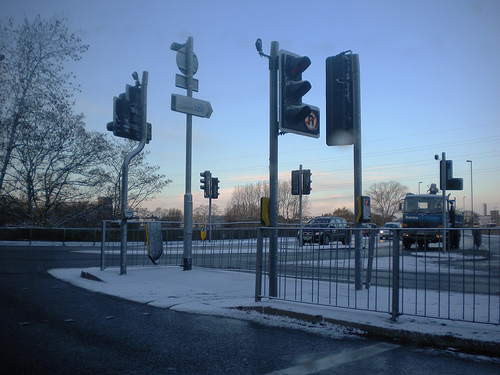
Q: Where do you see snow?
A: On the ground.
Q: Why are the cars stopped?
A: The light is red.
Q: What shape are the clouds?
A: Long and thin.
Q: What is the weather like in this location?
A: Cold.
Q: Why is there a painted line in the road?
A: To stop.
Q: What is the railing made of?
A: Metal.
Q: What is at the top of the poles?
A: Signs and traffic lights.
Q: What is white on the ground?
A: Snow.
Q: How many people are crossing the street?
A: None.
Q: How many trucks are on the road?
A: One.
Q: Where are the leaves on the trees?
A: It is winter.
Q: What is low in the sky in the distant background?
A: Clouds.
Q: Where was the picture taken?
A: On a street.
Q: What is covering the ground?
A: Snow.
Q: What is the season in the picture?
A: Winter.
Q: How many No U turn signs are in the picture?
A: 1.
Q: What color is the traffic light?
A: Red.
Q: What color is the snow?
A: White.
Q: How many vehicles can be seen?
A: 3.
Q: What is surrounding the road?
A: A fence.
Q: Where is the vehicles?
A: On the road.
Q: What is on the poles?
A: Street Lights.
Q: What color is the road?
A: Black.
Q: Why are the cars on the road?
A: The cars are driving.